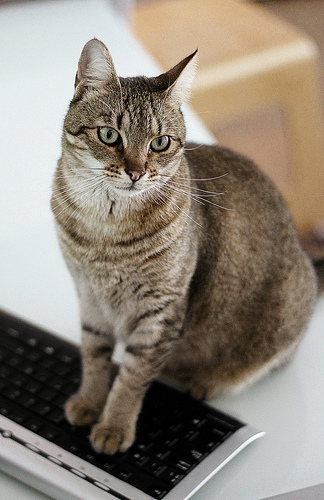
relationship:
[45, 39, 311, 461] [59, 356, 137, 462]
cat with paws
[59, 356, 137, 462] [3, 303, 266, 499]
paws on keyboard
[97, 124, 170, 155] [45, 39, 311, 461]
eyes of cat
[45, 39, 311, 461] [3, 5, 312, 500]
cat sitting on desk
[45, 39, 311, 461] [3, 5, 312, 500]
cat on desk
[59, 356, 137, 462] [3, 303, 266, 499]
paws resting on keyboard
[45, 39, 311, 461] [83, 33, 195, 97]
cat has ears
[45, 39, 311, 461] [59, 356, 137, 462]
cat has paws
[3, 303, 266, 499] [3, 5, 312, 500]
keyboard on desk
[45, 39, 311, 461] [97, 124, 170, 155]
cat has eyes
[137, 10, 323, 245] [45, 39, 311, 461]
floor behind cat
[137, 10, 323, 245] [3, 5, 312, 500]
floor behind desk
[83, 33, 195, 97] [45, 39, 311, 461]
ears of cat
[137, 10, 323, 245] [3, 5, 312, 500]
floor under desk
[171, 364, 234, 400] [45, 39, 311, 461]
paws under cat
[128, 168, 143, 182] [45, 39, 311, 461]
nose of cat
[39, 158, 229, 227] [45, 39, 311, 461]
whiskers of cat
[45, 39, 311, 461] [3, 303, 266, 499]
cat standing on keyboard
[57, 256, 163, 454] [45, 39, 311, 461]
legs of cat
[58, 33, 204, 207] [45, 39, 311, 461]
head of cat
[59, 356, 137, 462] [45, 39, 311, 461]
paws of cat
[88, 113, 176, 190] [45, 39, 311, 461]
face of cat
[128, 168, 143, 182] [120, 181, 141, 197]
nose and mouth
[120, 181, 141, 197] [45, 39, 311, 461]
mouth of cat